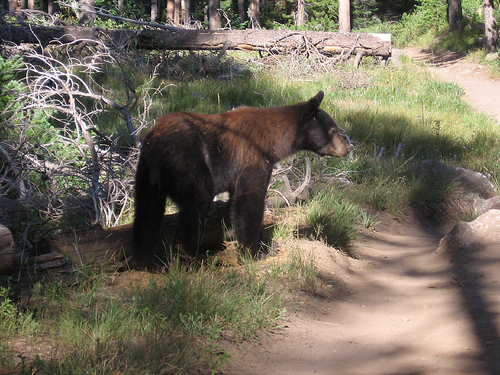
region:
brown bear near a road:
[117, 83, 362, 273]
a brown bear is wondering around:
[111, 74, 356, 274]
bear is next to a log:
[5, 80, 365, 302]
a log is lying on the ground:
[21, 196, 288, 307]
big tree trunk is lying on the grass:
[10, 11, 404, 70]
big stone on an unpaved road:
[420, 185, 496, 266]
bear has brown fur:
[119, 81, 366, 273]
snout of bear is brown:
[327, 134, 355, 166]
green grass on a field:
[155, 60, 441, 96]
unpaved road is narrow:
[408, 42, 498, 116]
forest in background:
[152, 2, 493, 29]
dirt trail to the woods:
[382, 36, 498, 116]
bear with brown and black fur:
[123, 86, 354, 276]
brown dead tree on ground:
[0, 23, 397, 62]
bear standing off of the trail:
[128, 89, 475, 304]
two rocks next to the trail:
[416, 159, 498, 252]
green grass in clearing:
[323, 71, 485, 191]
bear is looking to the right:
[147, 99, 362, 262]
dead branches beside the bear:
[36, 58, 246, 265]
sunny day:
[299, 34, 496, 116]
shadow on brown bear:
[152, 104, 263, 197]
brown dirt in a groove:
[315, 244, 404, 359]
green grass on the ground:
[144, 283, 273, 338]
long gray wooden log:
[76, 210, 291, 262]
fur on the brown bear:
[208, 113, 294, 157]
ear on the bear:
[286, 80, 334, 103]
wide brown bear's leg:
[224, 153, 287, 271]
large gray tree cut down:
[119, 13, 418, 65]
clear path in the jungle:
[423, 52, 482, 117]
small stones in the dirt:
[299, 274, 388, 321]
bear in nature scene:
[52, 61, 402, 300]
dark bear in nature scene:
[53, 59, 388, 313]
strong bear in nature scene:
[80, 68, 382, 283]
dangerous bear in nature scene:
[89, 62, 374, 297]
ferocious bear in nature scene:
[81, 56, 376, 320]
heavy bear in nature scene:
[101, 73, 378, 297]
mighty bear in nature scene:
[100, 66, 382, 319]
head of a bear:
[286, 83, 358, 174]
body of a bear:
[140, 107, 270, 192]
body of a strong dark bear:
[140, 103, 276, 204]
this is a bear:
[129, 80, 359, 280]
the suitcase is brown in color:
[132, 87, 369, 260]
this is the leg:
[176, 194, 224, 254]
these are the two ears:
[308, 88, 327, 107]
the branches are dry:
[1, 47, 119, 198]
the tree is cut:
[285, 30, 387, 60]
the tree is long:
[173, 32, 391, 50]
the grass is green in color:
[177, 267, 284, 335]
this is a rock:
[436, 217, 492, 253]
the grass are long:
[374, 66, 429, 98]